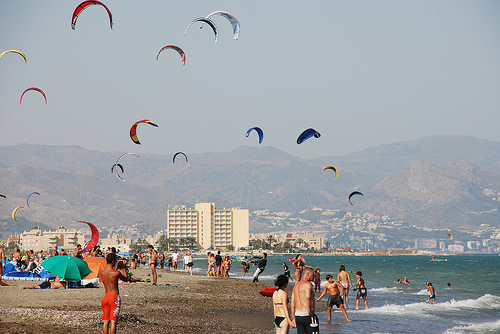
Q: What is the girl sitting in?
A: Car.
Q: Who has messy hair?
A: The girl.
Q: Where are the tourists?
A: On beach.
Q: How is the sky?
A: Dull.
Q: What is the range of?
A: Mountains.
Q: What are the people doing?
A: Flying kites.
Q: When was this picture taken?
A: Daytime.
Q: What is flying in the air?
A: Kites.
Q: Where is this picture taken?
A: At the beach.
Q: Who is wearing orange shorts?
A: The man in the front.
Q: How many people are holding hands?
A: Two.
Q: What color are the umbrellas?
A: Orange and teal.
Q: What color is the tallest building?
A: White.